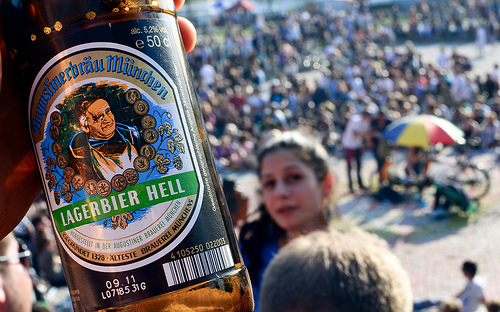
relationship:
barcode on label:
[162, 243, 235, 287] [48, 102, 220, 312]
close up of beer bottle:
[52, 52, 131, 312] [147, 257, 181, 312]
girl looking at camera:
[239, 131, 415, 312] [254, 152, 314, 263]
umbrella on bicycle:
[385, 115, 465, 145] [369, 158, 489, 199]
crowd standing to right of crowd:
[178, 1, 500, 311] [351, 100, 490, 115]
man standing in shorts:
[342, 107, 391, 196] [340, 143, 368, 167]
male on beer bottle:
[68, 96, 141, 182] [0, 0, 258, 311]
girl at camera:
[239, 131, 415, 312] [7, 2, 497, 306]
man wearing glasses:
[1, 230, 41, 310] [0, 238, 38, 270]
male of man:
[68, 96, 141, 182] [73, 91, 136, 173]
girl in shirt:
[239, 131, 415, 312] [242, 227, 283, 289]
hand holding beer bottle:
[3, 4, 207, 246] [0, 0, 258, 311]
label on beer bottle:
[9, 9, 270, 308] [0, 0, 258, 311]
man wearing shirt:
[341, 110, 374, 194] [337, 114, 377, 151]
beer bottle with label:
[0, 0, 258, 311] [19, 19, 254, 309]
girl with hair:
[247, 129, 362, 243] [236, 135, 341, 177]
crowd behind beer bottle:
[178, 1, 496, 183] [0, 0, 258, 311]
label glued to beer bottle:
[9, 9, 270, 308] [0, 0, 258, 311]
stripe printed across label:
[44, 168, 212, 237] [9, 9, 270, 308]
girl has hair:
[239, 131, 415, 312] [235, 206, 292, 264]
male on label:
[68, 96, 141, 182] [19, 19, 254, 309]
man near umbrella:
[341, 110, 374, 194] [379, 110, 473, 155]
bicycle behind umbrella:
[413, 144, 499, 200] [381, 108, 468, 162]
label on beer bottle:
[23, 15, 241, 311] [0, 0, 258, 311]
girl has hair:
[239, 131, 415, 312] [259, 127, 332, 182]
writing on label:
[32, 50, 166, 130] [19, 19, 254, 309]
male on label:
[74, 91, 140, 175] [31, 15, 244, 306]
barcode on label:
[162, 241, 233, 286] [19, 19, 254, 309]